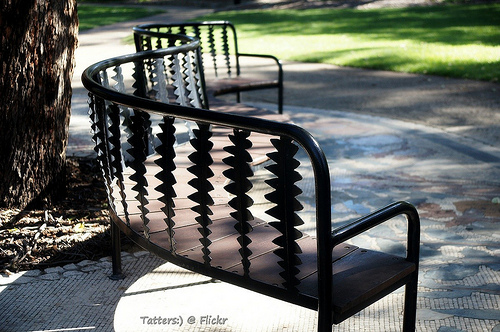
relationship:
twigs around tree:
[23, 201, 77, 258] [0, 0, 79, 210]